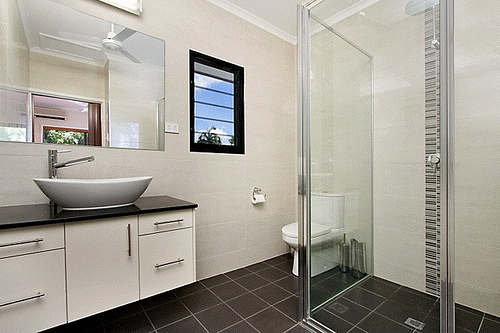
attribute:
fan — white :
[57, 20, 140, 66]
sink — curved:
[32, 176, 154, 211]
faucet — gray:
[42, 145, 99, 178]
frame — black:
[187, 48, 245, 154]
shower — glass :
[291, 9, 478, 319]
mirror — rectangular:
[7, 2, 189, 159]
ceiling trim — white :
[206, 1, 381, 46]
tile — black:
[138, 249, 358, 331]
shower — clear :
[294, 4, 499, 331]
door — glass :
[294, 15, 456, 331]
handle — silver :
[127, 222, 130, 256]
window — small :
[190, 59, 239, 149]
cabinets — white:
[10, 226, 215, 320]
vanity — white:
[0, 194, 198, 331]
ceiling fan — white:
[62, 25, 142, 67]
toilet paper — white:
[251, 192, 267, 206]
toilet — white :
[278, 168, 368, 283]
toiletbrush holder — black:
[339, 230, 349, 274]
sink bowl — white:
[31, 175, 156, 212]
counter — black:
[1, 193, 197, 229]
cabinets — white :
[4, 194, 204, 331]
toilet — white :
[272, 185, 353, 287]